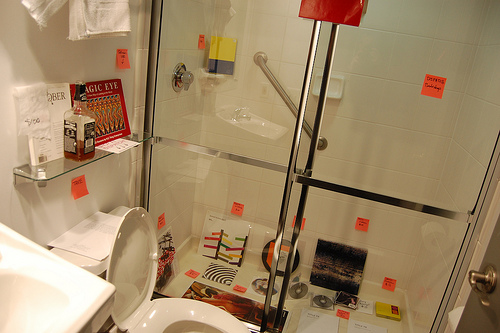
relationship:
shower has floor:
[147, 23, 499, 280] [153, 233, 413, 332]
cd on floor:
[312, 295, 333, 309] [153, 233, 413, 332]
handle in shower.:
[253, 52, 325, 150] [141, 0, 497, 330]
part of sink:
[12, 269, 69, 326] [1, 227, 103, 329]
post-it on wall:
[67, 172, 92, 200] [3, 5, 143, 232]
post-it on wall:
[417, 72, 448, 100] [151, 1, 498, 330]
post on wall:
[348, 218, 375, 244] [151, 1, 498, 330]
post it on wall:
[381, 274, 398, 294] [372, 265, 411, 302]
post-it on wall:
[420, 74, 447, 100] [193, 1, 490, 331]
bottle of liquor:
[62, 81, 96, 161] [63, 139, 93, 160]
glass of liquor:
[61, 84, 93, 166] [63, 139, 93, 160]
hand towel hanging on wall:
[21, 6, 56, 28] [3, 5, 143, 232]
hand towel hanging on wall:
[75, 21, 137, 42] [3, 5, 143, 232]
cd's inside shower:
[251, 273, 333, 310] [141, 0, 495, 328]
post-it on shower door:
[420, 74, 445, 96] [261, 2, 496, 329]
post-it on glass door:
[420, 74, 445, 96] [264, 0, 496, 328]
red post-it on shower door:
[421, 72, 444, 99] [261, 2, 496, 329]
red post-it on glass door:
[421, 72, 444, 99] [264, 0, 496, 328]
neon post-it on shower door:
[420, 74, 446, 95] [261, 2, 496, 329]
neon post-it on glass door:
[420, 74, 446, 95] [264, 0, 496, 328]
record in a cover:
[259, 225, 305, 282] [254, 229, 309, 279]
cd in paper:
[290, 282, 310, 301] [295, 295, 332, 331]